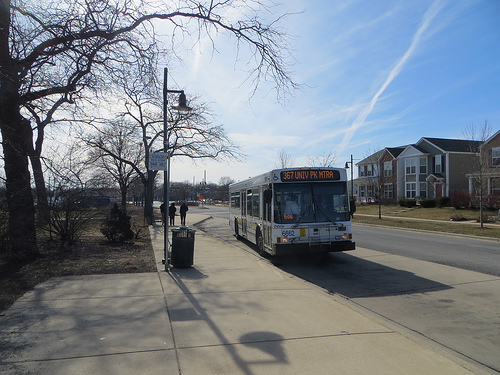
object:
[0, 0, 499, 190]
sky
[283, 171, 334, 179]
text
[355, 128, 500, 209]
house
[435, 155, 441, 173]
window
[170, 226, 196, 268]
trash can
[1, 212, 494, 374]
sidewalk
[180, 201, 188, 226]
person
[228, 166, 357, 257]
bus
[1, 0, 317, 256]
trees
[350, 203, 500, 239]
grass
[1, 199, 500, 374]
ground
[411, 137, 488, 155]
roof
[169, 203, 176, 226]
person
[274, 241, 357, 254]
bumper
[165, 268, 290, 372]
shadow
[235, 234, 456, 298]
shadow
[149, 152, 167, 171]
sign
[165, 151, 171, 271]
pole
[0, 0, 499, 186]
clouds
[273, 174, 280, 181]
handicap sign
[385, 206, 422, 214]
steps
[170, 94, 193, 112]
light post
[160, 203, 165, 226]
person